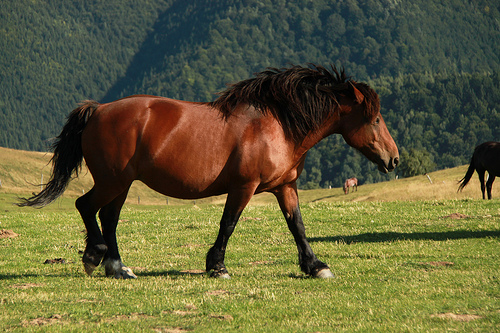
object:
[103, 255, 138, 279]
horse foot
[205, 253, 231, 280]
horse foot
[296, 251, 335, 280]
horse foot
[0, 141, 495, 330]
horse field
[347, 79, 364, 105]
ear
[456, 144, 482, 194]
tail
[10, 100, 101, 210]
tail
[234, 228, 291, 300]
grass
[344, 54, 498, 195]
tree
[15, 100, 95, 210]
hair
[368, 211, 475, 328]
grass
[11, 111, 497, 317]
field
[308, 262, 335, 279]
hoof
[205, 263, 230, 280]
hoof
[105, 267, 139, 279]
hoof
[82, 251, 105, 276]
hoof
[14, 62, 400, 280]
horse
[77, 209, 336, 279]
legs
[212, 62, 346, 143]
hair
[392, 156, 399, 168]
nose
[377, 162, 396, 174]
mouth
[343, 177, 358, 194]
horse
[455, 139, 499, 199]
horse